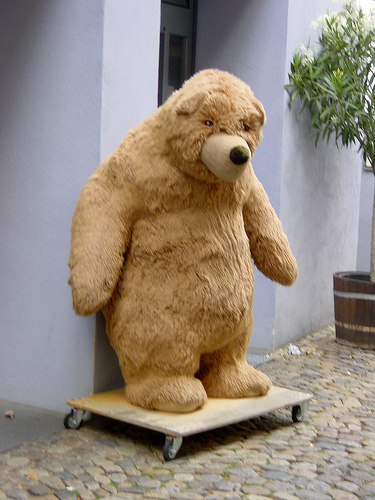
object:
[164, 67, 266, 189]
head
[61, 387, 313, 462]
wheelie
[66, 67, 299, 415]
bear